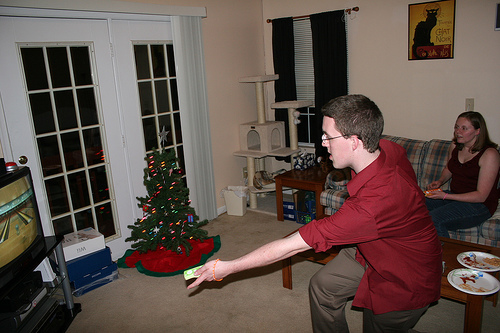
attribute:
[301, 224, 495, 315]
table — wooden, wodoen, brown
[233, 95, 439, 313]
boy — playing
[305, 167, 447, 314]
shirt — maroon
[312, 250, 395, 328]
pants — brown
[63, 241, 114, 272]
box — blue, white